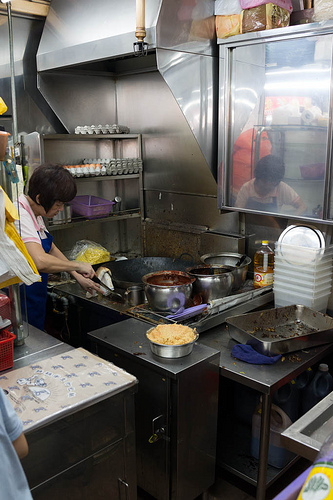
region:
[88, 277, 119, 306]
A woman with a knife in her hand.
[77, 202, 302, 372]
The kitchen is junky and dirty.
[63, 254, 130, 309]
The lady is cutting something.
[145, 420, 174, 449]
The handle on a container.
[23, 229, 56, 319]
The asian lady has on a blue apron.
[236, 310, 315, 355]
The silver pan is dirty.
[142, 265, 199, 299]
The pot has a brown sauce in it.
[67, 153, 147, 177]
Eggs sitting on the shelf next to the stove.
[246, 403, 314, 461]
A jug of oil uner the table.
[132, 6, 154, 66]
A fire sprinkler above the stove.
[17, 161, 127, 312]
woman with knife in hand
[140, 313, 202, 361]
food in round pan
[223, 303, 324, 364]
dirty metal rectangle pan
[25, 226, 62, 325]
blue apron on woman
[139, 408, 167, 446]
metal handle on door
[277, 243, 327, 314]
stack of plastic containers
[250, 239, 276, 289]
plastic bottle of oil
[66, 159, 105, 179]
eggs in cardboard carton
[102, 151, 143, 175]
stack of empty egg cartons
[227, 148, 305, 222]
reflection of woman on metal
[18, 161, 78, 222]
Woman's hair is brown.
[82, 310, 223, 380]
the counter is silver.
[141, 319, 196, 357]
yellow food in bowl.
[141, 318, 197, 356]
the bowl is silver.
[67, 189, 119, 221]
the container is purple.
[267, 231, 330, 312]
the containers are white.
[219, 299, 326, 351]
the pan is dirty.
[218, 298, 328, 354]
the pan is silver.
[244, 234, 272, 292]
the bottle is full.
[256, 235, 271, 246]
the cap is yellow.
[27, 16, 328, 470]
chef in commercial kitchen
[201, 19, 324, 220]
reflection of cook and shelves on panel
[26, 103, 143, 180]
white and brown eggs on metal shelves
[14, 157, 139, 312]
chef using cooking utensil in hand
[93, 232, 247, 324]
round pots next to blackened wok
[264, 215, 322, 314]
metal disk on top of plastic containers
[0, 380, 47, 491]
person standing in front of metal cabinet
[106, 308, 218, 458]
open pot of orange food on metal cabinet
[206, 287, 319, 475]
used roasting pan on metal table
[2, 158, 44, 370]
plastic bags and bin near cook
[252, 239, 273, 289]
large bottle of cooking oil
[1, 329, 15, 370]
corner of red plastic basket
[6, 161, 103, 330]
woman cleaning the stove top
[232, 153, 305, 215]
reflection of woman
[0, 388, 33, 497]
corner of person in blue shirt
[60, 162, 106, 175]
carton of brown eggs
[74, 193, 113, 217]
purple plastic bin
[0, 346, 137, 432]
white and blue tiled counter top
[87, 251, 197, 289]
giant wok on the stove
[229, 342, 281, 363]
blue dish rag